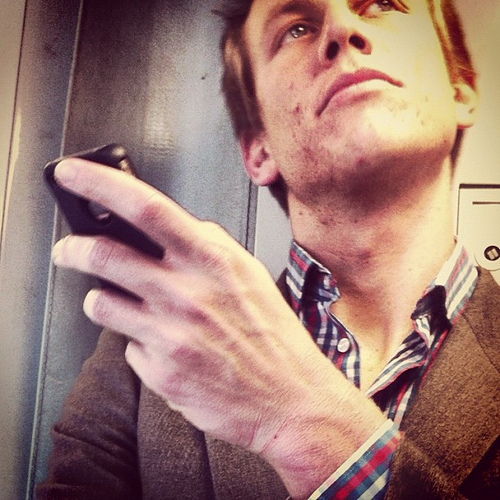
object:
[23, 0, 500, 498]
man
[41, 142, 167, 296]
cell phone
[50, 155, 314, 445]
hand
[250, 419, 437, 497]
cuff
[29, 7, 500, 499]
man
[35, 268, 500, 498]
coat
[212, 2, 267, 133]
hair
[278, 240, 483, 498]
shirt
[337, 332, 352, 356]
buttons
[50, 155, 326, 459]
mans hand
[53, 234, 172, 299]
middle finger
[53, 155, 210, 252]
index finger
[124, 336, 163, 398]
pinky finger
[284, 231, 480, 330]
collar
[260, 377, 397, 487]
wrist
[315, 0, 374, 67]
nose